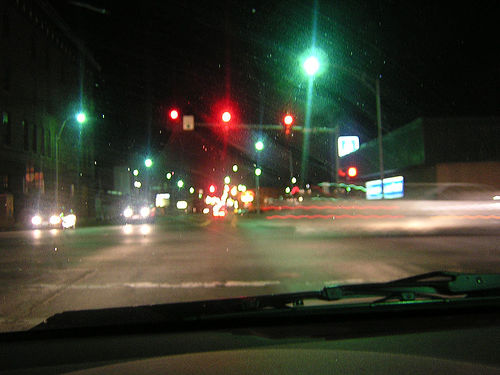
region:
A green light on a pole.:
[68, 94, 102, 144]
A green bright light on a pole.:
[61, 83, 118, 155]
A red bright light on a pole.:
[205, 90, 245, 140]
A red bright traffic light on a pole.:
[211, 94, 243, 144]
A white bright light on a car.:
[139, 205, 150, 218]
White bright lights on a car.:
[116, 203, 159, 225]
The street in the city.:
[125, 240, 314, 280]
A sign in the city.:
[331, 130, 366, 160]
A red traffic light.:
[162, 98, 184, 128]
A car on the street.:
[112, 194, 162, 226]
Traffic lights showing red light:
[163, 102, 347, 149]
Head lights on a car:
[120, 203, 165, 234]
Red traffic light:
[171, 108, 294, 140]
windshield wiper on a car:
[290, 270, 467, 317]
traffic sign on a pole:
[179, 113, 201, 139]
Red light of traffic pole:
[152, 98, 318, 146]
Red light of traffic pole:
[163, 106, 299, 135]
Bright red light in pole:
[211, 99, 243, 128]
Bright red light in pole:
[277, 108, 304, 140]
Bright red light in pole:
[167, 100, 187, 125]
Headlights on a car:
[120, 197, 160, 223]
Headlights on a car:
[31, 202, 84, 235]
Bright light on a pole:
[282, 33, 386, 204]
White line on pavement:
[26, 267, 268, 299]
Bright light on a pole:
[45, 103, 84, 240]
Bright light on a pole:
[115, 121, 165, 221]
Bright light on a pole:
[164, 170, 192, 218]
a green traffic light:
[294, 40, 329, 86]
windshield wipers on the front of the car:
[12, 268, 499, 332]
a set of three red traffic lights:
[163, 98, 300, 138]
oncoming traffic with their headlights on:
[21, 189, 164, 240]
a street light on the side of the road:
[53, 108, 94, 221]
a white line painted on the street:
[6, 275, 358, 290]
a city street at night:
[0, 210, 499, 318]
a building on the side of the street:
[0, 0, 107, 227]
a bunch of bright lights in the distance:
[193, 176, 270, 223]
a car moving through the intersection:
[284, 180, 499, 234]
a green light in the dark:
[293, 1, 328, 176]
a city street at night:
[5, 2, 497, 325]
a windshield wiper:
[26, 264, 498, 350]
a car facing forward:
[116, 193, 158, 224]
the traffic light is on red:
[164, 101, 305, 137]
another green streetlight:
[48, 106, 88, 230]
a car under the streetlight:
[27, 202, 80, 237]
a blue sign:
[357, 175, 411, 198]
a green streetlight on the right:
[334, 132, 364, 166]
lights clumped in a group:
[200, 174, 257, 221]